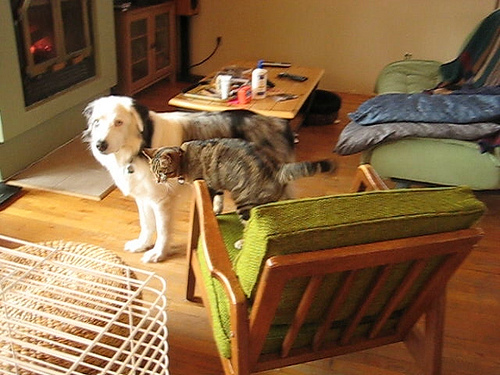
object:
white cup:
[214, 72, 233, 104]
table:
[167, 61, 324, 115]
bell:
[175, 175, 187, 185]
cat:
[144, 138, 344, 253]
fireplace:
[14, 0, 94, 81]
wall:
[1, 0, 119, 182]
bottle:
[251, 59, 267, 99]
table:
[168, 57, 324, 148]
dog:
[43, 90, 316, 263]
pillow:
[290, 63, 481, 217]